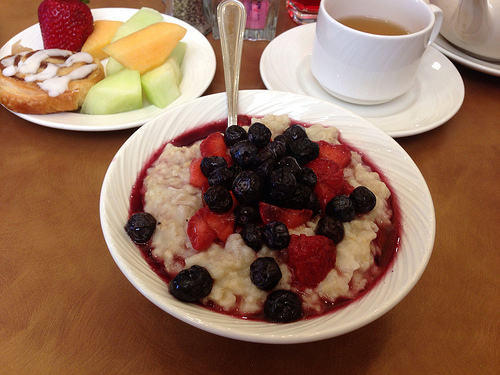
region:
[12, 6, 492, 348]
photograph of breakfast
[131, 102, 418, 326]
oatmeal with blueberries and strawberries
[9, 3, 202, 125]
small white round plate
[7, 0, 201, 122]
plate filled with fruit and a pastry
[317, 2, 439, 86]
white cup with coffee in it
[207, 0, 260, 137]
silver spoon in oatmeal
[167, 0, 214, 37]
glass pepper shaker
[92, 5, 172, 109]
slices of cantaloupe and melon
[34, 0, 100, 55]
one red strawberry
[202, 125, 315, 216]
pile of blueberries on top of strawberries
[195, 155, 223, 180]
blueberry on top of oatmeal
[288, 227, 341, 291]
strawberry on top of oatmeal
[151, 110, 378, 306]
oatmeal with fruit on top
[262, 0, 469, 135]
white cup on white saucer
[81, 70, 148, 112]
honey dew melon on plate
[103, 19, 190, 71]
cantaloupe on white plate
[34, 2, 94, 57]
red strawberry on white plate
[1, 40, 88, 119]
cinnamon roll on plate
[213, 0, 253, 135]
silver flat ware in bowl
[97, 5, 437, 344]
bowl of oatmeal with fruit on top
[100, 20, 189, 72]
a piece of cantaloupe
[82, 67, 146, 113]
a piece of honeydew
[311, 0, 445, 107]
the mug is white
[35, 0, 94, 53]
the strawberry is big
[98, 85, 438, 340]
a bowl of oatmeal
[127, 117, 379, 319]
blueberries in the bowl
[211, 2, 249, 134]
the handle is silver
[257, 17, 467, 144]
the plate under the mug is white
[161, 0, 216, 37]
a pepper shaker by the fruit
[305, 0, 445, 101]
the mug has tea in it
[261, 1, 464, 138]
white ceramic coffee cup and saucer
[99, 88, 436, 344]
bowl of oatmeal with fruit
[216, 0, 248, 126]
silver handle of spoon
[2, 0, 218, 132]
small plate of fresh fruit and danish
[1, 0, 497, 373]
breakfast served on table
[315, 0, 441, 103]
white cup filled with tea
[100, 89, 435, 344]
oakmeal with blackberries, blueberries and strawberries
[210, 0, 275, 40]
sugar holder with sugar substitute in pink packets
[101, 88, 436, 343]
white bowl with lip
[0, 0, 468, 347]
fruit, danish and oatmeal breakfast with tea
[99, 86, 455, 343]
bowl of oatmeal and fruit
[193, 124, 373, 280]
strawberries and blueberries on oatmeal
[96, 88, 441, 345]
white bowl of oatmeal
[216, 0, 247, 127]
spoon in bowl of oatmeal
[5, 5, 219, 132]
plate of melons and strawberry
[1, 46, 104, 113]
pastry on white plate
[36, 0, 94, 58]
strawberry on plate with melons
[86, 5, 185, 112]
slices of melons on plate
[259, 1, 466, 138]
coffee cup and saucer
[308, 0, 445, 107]
white coffee cup on saucer